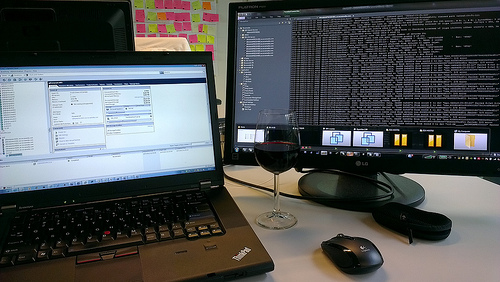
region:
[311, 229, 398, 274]
Gray and black computer mouse on desk.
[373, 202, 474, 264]
Black zipper case on desk.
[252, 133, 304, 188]
Red wine in glass.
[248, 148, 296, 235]
Wine glass is sitting on table.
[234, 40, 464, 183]
Large computer monitor is on desk.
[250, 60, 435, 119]
Computer monitor is turned on.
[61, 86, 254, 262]
Black laptop on desk.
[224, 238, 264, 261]
White writing on laptop.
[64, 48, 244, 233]
Laptop is turned on.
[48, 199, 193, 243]
Laptop has black buttons.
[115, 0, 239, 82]
colored sticky notes on a wall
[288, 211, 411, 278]
a black computer mouse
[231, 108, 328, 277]
a wine glass with wine in it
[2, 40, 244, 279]
a black laptop on a desk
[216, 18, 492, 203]
a black computer screen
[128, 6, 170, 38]
a yellow sticky note on a wall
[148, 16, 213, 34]
a pink sticky note on a wall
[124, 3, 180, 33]
a orange sticky note on a wall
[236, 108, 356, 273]
a wine glass on a table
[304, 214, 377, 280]
a black mouse on a table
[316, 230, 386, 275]
A black wireless mouse.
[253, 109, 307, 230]
A glass of wine.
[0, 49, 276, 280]
A open lap top.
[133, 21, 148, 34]
A pink sticky note.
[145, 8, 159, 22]
A yellow sticky note.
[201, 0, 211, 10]
A orange sticky note.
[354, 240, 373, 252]
Logo on a computer mouse.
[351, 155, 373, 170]
Logo on a computer monitor.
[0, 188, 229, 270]
Keyboard on a laptop.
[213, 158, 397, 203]
A black long cord.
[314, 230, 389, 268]
a black mouse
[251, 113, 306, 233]
a whine glass on the desk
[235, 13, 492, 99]
a monitor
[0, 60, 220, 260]
a laptop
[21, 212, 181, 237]
keyboard on the laptop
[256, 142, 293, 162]
liquid in the glass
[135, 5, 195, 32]
post its on the wall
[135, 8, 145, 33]
pink post its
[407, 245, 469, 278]
the desk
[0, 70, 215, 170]
the screen of the laptop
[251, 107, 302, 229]
A clear wine glass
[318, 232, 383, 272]
A black wireless mouse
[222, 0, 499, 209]
A larte computer monitor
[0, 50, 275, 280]
A black laptop computer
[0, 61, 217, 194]
A lit computer screen.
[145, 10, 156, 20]
A yellow post it note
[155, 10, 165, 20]
An orange post it note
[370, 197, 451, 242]
A black case with zipper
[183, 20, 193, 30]
A pink post it note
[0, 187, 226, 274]
Black laptop keyboard